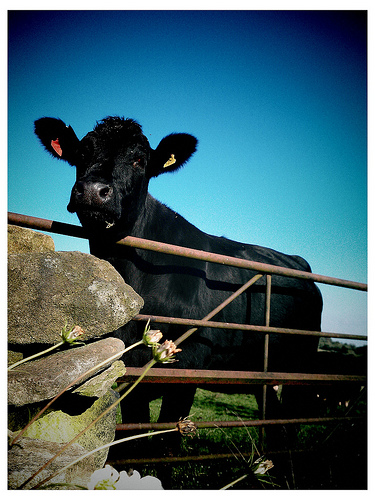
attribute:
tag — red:
[36, 114, 84, 184]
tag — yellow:
[137, 144, 213, 183]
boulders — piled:
[36, 247, 142, 474]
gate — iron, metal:
[174, 242, 270, 381]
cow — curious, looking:
[62, 139, 314, 384]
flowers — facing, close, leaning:
[77, 289, 208, 410]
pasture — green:
[150, 375, 333, 476]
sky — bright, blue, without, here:
[173, 45, 300, 179]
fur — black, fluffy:
[86, 111, 156, 145]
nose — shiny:
[50, 176, 116, 223]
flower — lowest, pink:
[174, 435, 290, 494]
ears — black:
[29, 107, 251, 217]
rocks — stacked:
[22, 246, 187, 457]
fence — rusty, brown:
[25, 210, 104, 324]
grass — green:
[128, 353, 264, 467]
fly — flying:
[17, 170, 71, 204]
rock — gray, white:
[28, 360, 119, 434]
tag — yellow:
[160, 152, 178, 169]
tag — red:
[49, 136, 64, 157]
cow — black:
[33, 111, 324, 479]